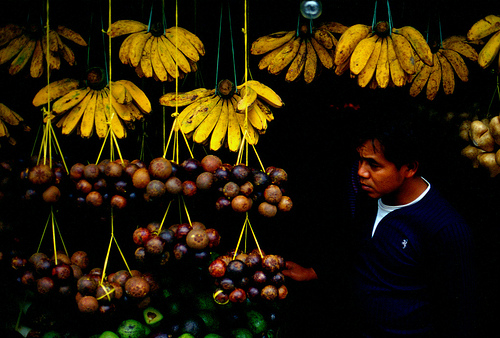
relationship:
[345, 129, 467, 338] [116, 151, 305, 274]
man looking at fruit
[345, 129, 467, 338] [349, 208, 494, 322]
man in shirt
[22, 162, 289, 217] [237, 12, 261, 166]
fruit hanging on string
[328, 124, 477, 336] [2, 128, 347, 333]
man looking at fruit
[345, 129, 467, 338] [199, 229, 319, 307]
man touching fruit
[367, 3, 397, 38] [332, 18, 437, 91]
string holding bananas